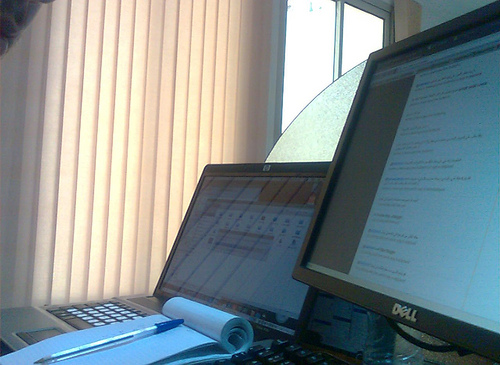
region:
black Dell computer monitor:
[294, 2, 498, 363]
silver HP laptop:
[1, 159, 333, 364]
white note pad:
[1, 294, 254, 364]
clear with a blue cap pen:
[28, 316, 186, 363]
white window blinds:
[1, 0, 284, 299]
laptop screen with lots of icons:
[153, 160, 331, 337]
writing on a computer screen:
[348, 62, 498, 308]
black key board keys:
[194, 337, 351, 364]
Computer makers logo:
[385, 294, 422, 327]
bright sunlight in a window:
[280, 0, 390, 137]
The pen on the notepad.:
[34, 316, 192, 355]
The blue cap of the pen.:
[147, 319, 187, 328]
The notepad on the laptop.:
[13, 294, 247, 364]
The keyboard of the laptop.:
[60, 297, 170, 337]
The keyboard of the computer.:
[220, 346, 336, 363]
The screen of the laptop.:
[161, 170, 304, 330]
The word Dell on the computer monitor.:
[391, 303, 420, 320]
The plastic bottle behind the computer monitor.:
[365, 308, 426, 363]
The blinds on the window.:
[20, 3, 265, 292]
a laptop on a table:
[47, 96, 297, 354]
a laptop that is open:
[65, 154, 289, 358]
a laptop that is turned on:
[67, 109, 277, 357]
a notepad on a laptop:
[68, 183, 351, 361]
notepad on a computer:
[92, 258, 292, 363]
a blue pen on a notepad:
[84, 266, 168, 354]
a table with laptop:
[166, 69, 496, 298]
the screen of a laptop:
[196, 153, 300, 333]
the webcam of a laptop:
[259, 162, 269, 182]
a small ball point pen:
[45, 313, 196, 362]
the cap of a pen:
[153, 309, 180, 332]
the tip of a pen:
[30, 353, 45, 364]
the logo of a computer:
[371, 300, 421, 331]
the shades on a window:
[53, 140, 165, 217]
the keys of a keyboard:
[54, 293, 129, 326]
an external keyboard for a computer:
[257, 333, 309, 361]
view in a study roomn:
[72, 124, 366, 353]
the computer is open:
[374, 120, 496, 269]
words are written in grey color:
[376, 293, 425, 335]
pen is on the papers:
[61, 304, 201, 331]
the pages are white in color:
[55, 314, 239, 352]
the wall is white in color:
[52, 13, 221, 175]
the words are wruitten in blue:
[193, 201, 288, 278]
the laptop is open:
[83, 232, 278, 344]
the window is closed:
[274, 3, 360, 75]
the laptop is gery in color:
[38, 279, 139, 324]